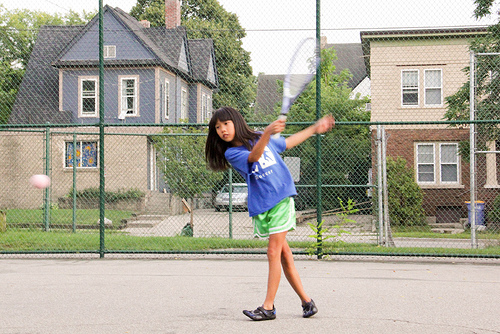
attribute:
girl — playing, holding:
[200, 96, 342, 327]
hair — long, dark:
[234, 123, 258, 143]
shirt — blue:
[256, 179, 288, 211]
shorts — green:
[255, 214, 307, 235]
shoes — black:
[244, 296, 332, 326]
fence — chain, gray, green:
[117, 34, 167, 94]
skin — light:
[291, 133, 302, 145]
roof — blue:
[39, 27, 55, 56]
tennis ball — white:
[38, 157, 62, 196]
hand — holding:
[268, 109, 291, 137]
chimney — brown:
[157, 1, 192, 30]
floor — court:
[114, 295, 175, 318]